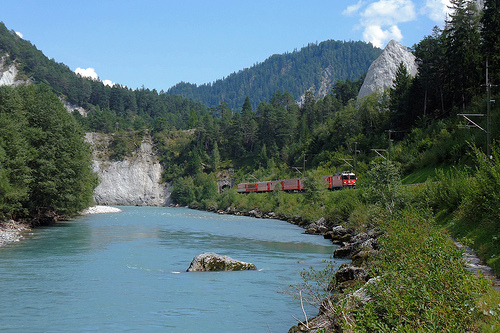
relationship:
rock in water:
[185, 252, 258, 272] [78, 227, 309, 330]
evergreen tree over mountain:
[19, 70, 100, 234] [198, 43, 462, 153]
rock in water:
[185, 252, 258, 272] [95, 200, 307, 330]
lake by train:
[0, 201, 354, 332] [200, 160, 390, 207]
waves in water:
[111, 220, 234, 255] [60, 288, 207, 323]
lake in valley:
[36, 224, 300, 327] [15, 83, 471, 315]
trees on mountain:
[207, 139, 221, 173] [194, 47, 418, 145]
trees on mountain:
[5, 80, 97, 225] [71, 82, 424, 182]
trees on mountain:
[207, 139, 221, 173] [181, 37, 424, 95]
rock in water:
[182, 240, 256, 282] [43, 245, 169, 325]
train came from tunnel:
[233, 162, 368, 196] [179, 157, 234, 198]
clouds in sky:
[364, 5, 424, 40] [80, 13, 217, 47]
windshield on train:
[333, 171, 363, 181] [204, 169, 360, 196]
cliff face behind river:
[85, 129, 177, 207] [3, 203, 352, 332]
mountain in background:
[2, 22, 429, 117] [1, 0, 398, 112]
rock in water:
[185, 252, 258, 272] [93, 213, 306, 330]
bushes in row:
[316, 202, 493, 332] [329, 197, 485, 331]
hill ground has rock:
[78, 203, 116, 216] [187, 250, 259, 270]